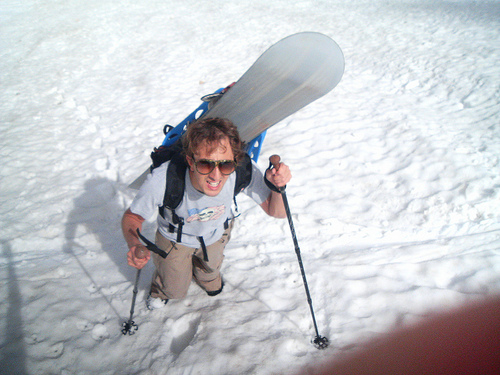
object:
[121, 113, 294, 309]
man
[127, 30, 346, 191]
snowboard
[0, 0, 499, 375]
snow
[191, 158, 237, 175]
sunglasses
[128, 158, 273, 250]
shirt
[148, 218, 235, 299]
pants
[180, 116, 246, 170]
hair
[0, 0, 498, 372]
ground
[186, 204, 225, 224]
skull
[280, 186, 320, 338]
black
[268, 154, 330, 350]
pole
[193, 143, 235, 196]
face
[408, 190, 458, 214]
footprints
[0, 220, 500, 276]
track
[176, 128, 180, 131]
blue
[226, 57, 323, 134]
striped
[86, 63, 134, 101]
white